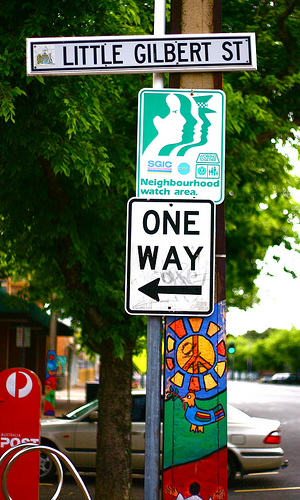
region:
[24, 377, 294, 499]
A beige car in the street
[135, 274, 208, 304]
Black arrow pointing left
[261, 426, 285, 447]
Red rear light of the car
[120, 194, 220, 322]
A black and white One Way sign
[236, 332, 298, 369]
Green trees in the background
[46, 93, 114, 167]
Green leaves on a tree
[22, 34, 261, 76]
Black and white street sign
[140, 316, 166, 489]
Gray post holding up signs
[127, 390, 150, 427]
Window of a car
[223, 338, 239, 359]
A traffic light is lit up green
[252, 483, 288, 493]
yellow line on the street.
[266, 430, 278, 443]
tail light of the car.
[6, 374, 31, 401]
white logo on red surface.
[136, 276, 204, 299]
black arrow on sign.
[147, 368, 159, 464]
metal post supporting sign.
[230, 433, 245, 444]
latch to gas tank.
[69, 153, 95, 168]
leaves on the tree.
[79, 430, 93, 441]
tan driver's side door.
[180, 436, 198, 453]
green paint on surface.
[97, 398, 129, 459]
trunk of the tree.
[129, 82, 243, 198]
Four profiles on a sign.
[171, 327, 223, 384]
Peace sign on the post.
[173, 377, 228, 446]
Hand painted bird on a post.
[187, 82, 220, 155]
Checkered brim on the hat.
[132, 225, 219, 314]
Graffitti on street sign.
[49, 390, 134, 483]
Gold car parked on the street.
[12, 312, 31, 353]
Sign on side of building.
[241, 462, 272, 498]
Yellow parking stripes on road.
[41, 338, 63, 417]
Hand painted decorated pole.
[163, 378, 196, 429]
Branch in birds mouth.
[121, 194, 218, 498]
one way sign on pole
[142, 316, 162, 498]
a grey pole for signs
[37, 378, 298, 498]
pavement is grey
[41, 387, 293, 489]
a tan car in lot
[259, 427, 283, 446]
red tail light on car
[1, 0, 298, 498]
a tree on the side of car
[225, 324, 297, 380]
trees along side the street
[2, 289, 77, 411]
a building in front of car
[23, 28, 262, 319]
three signs in the air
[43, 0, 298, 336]
the sky is clear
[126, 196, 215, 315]
One-way street sign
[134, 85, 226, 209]
Neighborhood watch street sign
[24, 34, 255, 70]
Street sign for Little Gilbert Street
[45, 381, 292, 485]
Car parked in a parking spot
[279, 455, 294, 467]
Trailer hitch on back of car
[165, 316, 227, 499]
Graffiti on a utility pole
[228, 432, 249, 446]
Gas filler door on a passenger car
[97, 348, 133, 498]
Trunk of a tree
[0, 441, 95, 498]
Bicycle rack to lock your bike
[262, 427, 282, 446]
Taillights on a passenger car